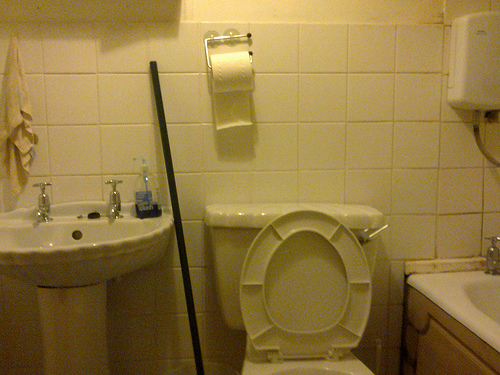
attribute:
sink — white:
[1, 196, 176, 373]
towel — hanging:
[4, 33, 49, 193]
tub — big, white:
[398, 269, 496, 371]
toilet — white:
[230, 202, 382, 374]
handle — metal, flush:
[358, 222, 390, 244]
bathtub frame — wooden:
[401, 294, 498, 374]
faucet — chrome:
[30, 180, 55, 227]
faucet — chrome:
[101, 176, 124, 226]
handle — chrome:
[366, 221, 392, 236]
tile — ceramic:
[12, 10, 497, 262]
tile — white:
[349, 72, 395, 124]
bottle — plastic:
[131, 155, 163, 218]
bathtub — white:
[411, 271, 499, 343]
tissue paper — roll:
[211, 36, 273, 121]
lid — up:
[255, 209, 377, 320]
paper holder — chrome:
[200, 26, 254, 61]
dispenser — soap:
[130, 157, 162, 222]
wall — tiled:
[302, 62, 394, 150]